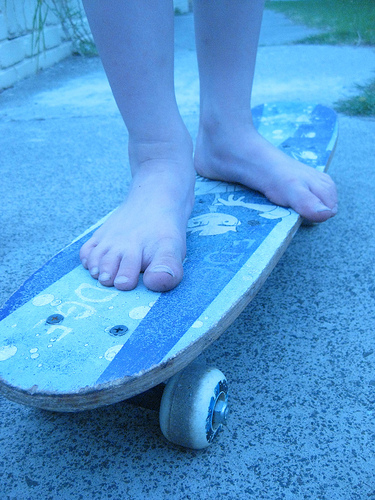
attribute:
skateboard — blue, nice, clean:
[1, 96, 343, 447]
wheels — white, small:
[160, 369, 237, 444]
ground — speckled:
[220, 3, 373, 452]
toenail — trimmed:
[310, 201, 333, 211]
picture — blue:
[6, 8, 372, 499]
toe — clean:
[304, 188, 329, 220]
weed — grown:
[63, 13, 97, 65]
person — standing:
[80, 3, 341, 288]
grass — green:
[269, 1, 374, 121]